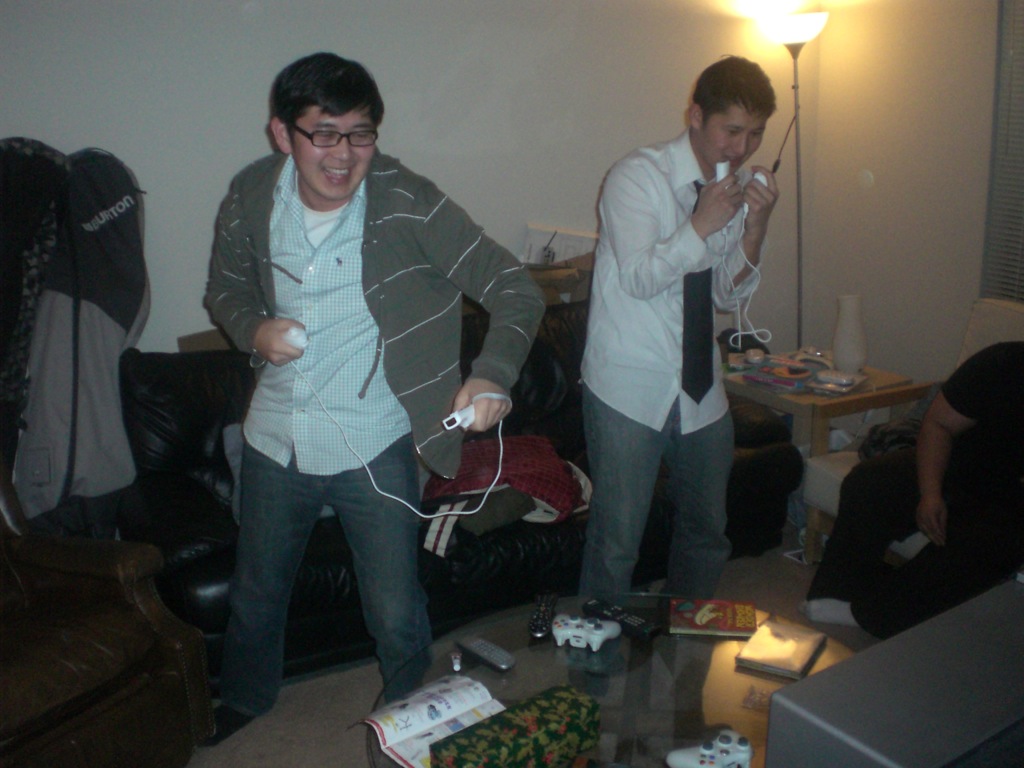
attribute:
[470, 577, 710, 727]
table — circular, glass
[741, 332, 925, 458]
table — brown, end